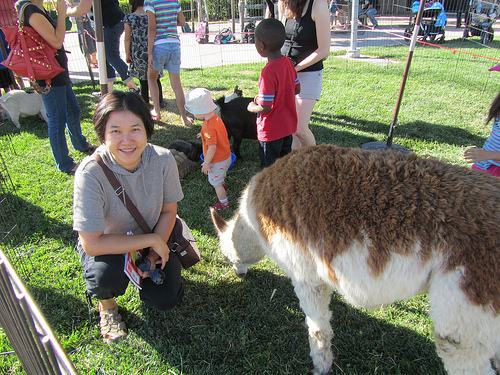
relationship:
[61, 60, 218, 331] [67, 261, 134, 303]
woman with short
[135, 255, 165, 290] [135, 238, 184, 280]
sunglasses in hand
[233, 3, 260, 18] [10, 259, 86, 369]
fence on side